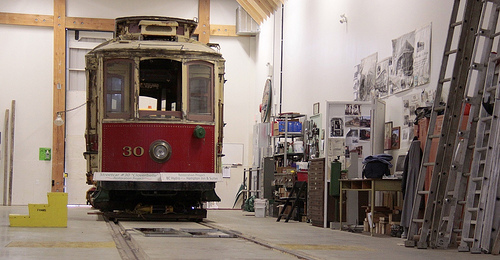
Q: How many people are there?
A: None.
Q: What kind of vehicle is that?
A: Trolley.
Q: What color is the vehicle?
A: Red.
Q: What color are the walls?
A: White.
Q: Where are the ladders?
A: By the walls.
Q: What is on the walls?
A: Drawings.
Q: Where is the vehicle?
A: By the wall.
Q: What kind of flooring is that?
A: Concrete.